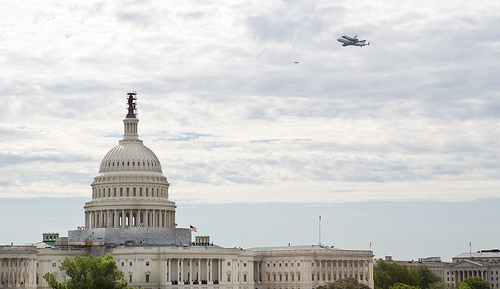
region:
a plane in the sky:
[334, 28, 376, 53]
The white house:
[0, 86, 381, 287]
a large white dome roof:
[94, 140, 180, 202]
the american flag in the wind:
[186, 222, 201, 242]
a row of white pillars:
[315, 256, 380, 286]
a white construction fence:
[66, 224, 196, 248]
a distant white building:
[447, 245, 498, 286]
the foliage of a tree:
[36, 246, 131, 287]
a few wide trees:
[366, 256, 448, 287]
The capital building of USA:
[0, 91, 382, 283]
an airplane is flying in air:
[333, 28, 370, 51]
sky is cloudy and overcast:
[4, 2, 499, 260]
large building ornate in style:
[3, 78, 381, 286]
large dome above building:
[70, 83, 184, 233]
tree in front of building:
[41, 249, 127, 287]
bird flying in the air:
[289, 57, 299, 67]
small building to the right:
[441, 244, 499, 284]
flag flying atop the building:
[186, 223, 198, 235]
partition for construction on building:
[63, 217, 199, 252]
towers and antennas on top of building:
[120, 87, 140, 122]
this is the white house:
[77, 129, 199, 246]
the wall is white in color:
[262, 251, 313, 286]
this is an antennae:
[120, 88, 139, 115]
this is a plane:
[331, 25, 373, 50]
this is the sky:
[273, 92, 369, 161]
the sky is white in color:
[225, 78, 343, 181]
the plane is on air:
[333, 28, 369, 50]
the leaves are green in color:
[62, 252, 113, 280]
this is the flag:
[185, 223, 197, 231]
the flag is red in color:
[185, 222, 195, 232]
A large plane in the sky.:
[336, 25, 370, 50]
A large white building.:
[1, 89, 371, 286]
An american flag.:
[188, 222, 200, 234]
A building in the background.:
[375, 238, 499, 288]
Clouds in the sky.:
[0, 1, 499, 199]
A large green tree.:
[42, 250, 128, 287]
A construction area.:
[64, 223, 199, 251]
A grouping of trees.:
[372, 254, 492, 287]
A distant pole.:
[317, 210, 323, 249]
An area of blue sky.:
[0, 193, 499, 268]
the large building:
[1, 91, 374, 288]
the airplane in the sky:
[337, 34, 370, 50]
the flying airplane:
[335, 34, 370, 49]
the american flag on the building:
[188, 224, 196, 243]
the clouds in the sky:
[1, 1, 498, 262]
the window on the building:
[145, 272, 150, 281]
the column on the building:
[135, 208, 140, 225]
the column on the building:
[196, 259, 201, 284]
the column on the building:
[119, 209, 125, 226]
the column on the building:
[167, 257, 171, 284]